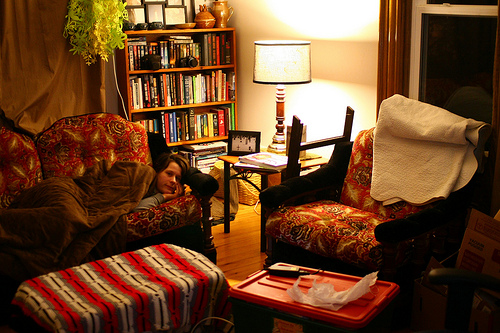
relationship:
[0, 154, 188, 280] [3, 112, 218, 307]
woman laying on couch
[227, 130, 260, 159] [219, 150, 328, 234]
frame on top of table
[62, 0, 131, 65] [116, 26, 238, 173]
plant next to bookcase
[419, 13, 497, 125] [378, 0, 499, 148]
window has frame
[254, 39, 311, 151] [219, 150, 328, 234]
lamp on top of table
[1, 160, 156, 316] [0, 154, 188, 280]
cover on top of woman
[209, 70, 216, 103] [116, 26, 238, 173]
book inside of bookcase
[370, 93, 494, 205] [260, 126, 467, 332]
blanket on top of chair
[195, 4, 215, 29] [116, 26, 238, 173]
pot on top of bookcase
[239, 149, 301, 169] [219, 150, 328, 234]
magazine on top of table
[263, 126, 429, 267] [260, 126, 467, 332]
cushion on top of chair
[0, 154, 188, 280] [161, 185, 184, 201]
woman has hand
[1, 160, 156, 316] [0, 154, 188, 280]
cover covering woman